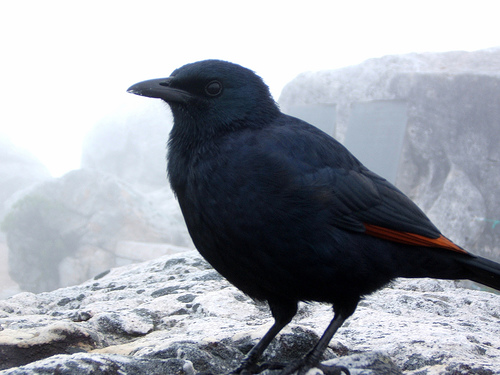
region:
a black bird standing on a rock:
[111, 58, 488, 359]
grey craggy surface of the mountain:
[427, 52, 493, 234]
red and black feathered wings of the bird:
[313, 167, 467, 262]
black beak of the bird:
[125, 73, 190, 108]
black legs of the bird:
[234, 300, 354, 372]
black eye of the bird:
[199, 74, 231, 103]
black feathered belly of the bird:
[211, 143, 308, 278]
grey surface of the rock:
[64, 264, 178, 374]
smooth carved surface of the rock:
[334, 87, 424, 180]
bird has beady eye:
[183, 62, 247, 108]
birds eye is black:
[201, 82, 232, 111]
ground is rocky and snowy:
[70, 275, 213, 345]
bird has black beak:
[123, 71, 220, 111]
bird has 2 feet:
[236, 288, 383, 374]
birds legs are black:
[238, 299, 384, 364]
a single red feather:
[357, 205, 462, 260]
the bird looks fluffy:
[138, 63, 362, 250]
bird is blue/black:
[176, 89, 371, 263]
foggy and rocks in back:
[341, 52, 465, 202]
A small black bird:
[125, 54, 473, 372]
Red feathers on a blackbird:
[367, 218, 465, 256]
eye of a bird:
[196, 74, 232, 110]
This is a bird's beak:
[127, 69, 199, 118]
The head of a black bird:
[110, 53, 291, 129]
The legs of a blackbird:
[218, 283, 400, 373]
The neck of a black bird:
[167, 106, 310, 153]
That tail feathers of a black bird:
[369, 176, 496, 288]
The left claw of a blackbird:
[256, 349, 357, 374]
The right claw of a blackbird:
[196, 352, 291, 374]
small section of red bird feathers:
[361, 213, 468, 256]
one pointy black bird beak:
[123, 79, 179, 106]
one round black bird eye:
[204, 72, 226, 97]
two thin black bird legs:
[226, 302, 350, 374]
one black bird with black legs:
[125, 48, 499, 373]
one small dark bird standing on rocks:
[125, 56, 494, 374]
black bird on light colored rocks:
[128, 54, 480, 374]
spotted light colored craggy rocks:
[16, 274, 218, 366]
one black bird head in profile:
[126, 56, 280, 129]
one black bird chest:
[166, 149, 248, 249]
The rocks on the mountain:
[8, 271, 221, 370]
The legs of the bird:
[231, 311, 350, 366]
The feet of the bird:
[208, 333, 363, 373]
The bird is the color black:
[121, 57, 476, 313]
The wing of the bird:
[228, 134, 464, 267]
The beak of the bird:
[122, 66, 202, 111]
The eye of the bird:
[196, 75, 226, 101]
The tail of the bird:
[396, 225, 498, 307]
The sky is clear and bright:
[17, 11, 480, 57]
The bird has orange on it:
[346, 207, 471, 259]